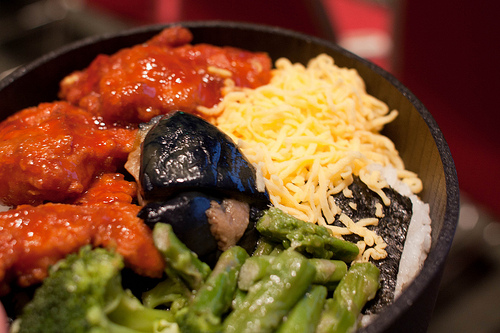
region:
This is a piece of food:
[139, 110, 275, 254]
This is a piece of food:
[207, 70, 399, 200]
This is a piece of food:
[210, 240, 355, 322]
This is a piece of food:
[45, 245, 166, 329]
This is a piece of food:
[10, 101, 121, 198]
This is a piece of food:
[78, 26, 265, 117]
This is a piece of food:
[247, 181, 366, 327]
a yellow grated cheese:
[202, 66, 314, 255]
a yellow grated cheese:
[234, 99, 407, 222]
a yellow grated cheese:
[203, 82, 435, 267]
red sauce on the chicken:
[24, 45, 240, 133]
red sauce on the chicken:
[10, 88, 132, 225]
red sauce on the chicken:
[0, 187, 200, 292]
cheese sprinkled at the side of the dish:
[227, 54, 419, 250]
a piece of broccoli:
[17, 250, 157, 330]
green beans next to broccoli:
[153, 216, 375, 327]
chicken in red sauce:
[0, 31, 273, 268]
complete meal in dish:
[2, 25, 428, 330]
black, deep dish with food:
[0, 23, 459, 328]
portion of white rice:
[356, 163, 430, 318]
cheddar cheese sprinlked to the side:
[211, 55, 418, 245]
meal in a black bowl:
[3, 30, 430, 330]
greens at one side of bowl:
[144, 212, 375, 331]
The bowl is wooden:
[1, 20, 461, 330]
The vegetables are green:
[18, 208, 377, 331]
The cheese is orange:
[240, 89, 385, 192]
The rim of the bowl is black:
[436, 75, 461, 310]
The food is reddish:
[3, 98, 132, 240]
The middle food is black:
[145, 120, 256, 241]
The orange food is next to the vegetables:
[7, 111, 147, 331]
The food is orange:
[5, 101, 130, 246]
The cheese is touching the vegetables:
[252, 90, 378, 317]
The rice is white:
[397, 196, 426, 281]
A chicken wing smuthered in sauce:
[1, 103, 138, 207]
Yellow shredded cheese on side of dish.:
[214, 50, 429, 263]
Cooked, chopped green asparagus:
[155, 204, 380, 331]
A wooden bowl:
[0, 19, 460, 331]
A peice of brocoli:
[16, 246, 172, 332]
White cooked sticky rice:
[378, 166, 431, 297]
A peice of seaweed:
[313, 163, 411, 323]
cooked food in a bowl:
[0, 17, 460, 327]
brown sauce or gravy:
[202, 195, 247, 250]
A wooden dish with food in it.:
[0, 19, 460, 331]